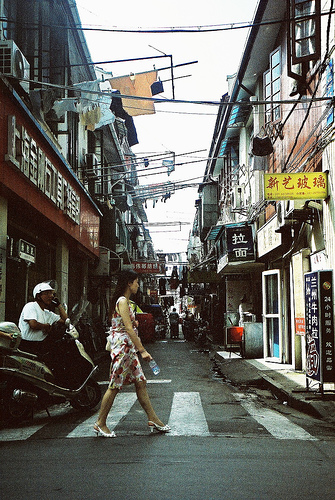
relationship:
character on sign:
[309, 273, 317, 287] [303, 271, 332, 380]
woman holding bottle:
[104, 272, 181, 422] [142, 355, 161, 376]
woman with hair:
[91, 271, 172, 435] [102, 267, 135, 313]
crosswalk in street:
[1, 389, 323, 444] [6, 324, 330, 498]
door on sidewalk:
[261, 268, 291, 363] [215, 347, 334, 409]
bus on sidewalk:
[303, 266, 331, 390] [204, 390, 312, 490]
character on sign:
[311, 316, 318, 328] [308, 271, 318, 288]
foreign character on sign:
[306, 278, 316, 360] [296, 260, 333, 409]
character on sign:
[232, 247, 249, 257] [225, 225, 254, 259]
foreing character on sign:
[322, 325, 332, 334] [316, 268, 333, 385]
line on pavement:
[166, 386, 211, 436] [2, 443, 330, 498]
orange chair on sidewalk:
[226, 325, 243, 360] [200, 330, 334, 432]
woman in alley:
[166, 305, 180, 339] [0, 325, 334, 438]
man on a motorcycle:
[17, 278, 85, 389] [2, 317, 101, 426]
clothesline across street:
[71, 141, 231, 214] [6, 324, 330, 498]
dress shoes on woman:
[87, 418, 172, 440] [83, 266, 175, 438]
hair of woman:
[112, 266, 134, 302] [99, 265, 156, 382]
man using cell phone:
[19, 281, 84, 389] [50, 297, 56, 304]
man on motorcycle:
[17, 278, 85, 389] [0, 301, 104, 426]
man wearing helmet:
[17, 278, 85, 389] [30, 282, 54, 297]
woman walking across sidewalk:
[91, 271, 172, 435] [0, 330, 335, 499]